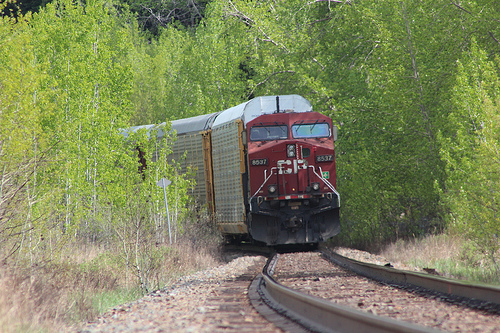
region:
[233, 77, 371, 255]
front of the train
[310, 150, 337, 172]
number on the front of the train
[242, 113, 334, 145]
windows on front of train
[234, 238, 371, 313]
track under the train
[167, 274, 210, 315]
rocks next to the track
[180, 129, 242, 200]
side of the train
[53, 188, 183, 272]
branches next to track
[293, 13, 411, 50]
leaves on the tree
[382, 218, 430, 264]
shadow on the ground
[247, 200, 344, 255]
bottom of the train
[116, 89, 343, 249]
A train with red paint on the front.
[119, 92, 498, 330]
A train traveling down train tracks.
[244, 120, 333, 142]
Two windows on the front of a train.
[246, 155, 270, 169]
A number in white letters.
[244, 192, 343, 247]
A black metal plate on the bottom of a train.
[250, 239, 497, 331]
Curvy train tracks.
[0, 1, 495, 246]
A large amount of trees that are mostly green.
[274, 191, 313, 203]
Red and white paint.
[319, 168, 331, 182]
A small green and white symbol.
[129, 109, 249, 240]
Cars of a train.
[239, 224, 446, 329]
These are train tracks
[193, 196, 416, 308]
The tracks are rusty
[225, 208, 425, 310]
The tracks are made of metal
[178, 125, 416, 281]
This is a large train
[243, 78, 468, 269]
The train is red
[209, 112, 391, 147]
These are two windows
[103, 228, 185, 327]
These are tiny stones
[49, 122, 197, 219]
These are old bushes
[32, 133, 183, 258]
The trees are very light green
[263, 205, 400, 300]
This part of the train is black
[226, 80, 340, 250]
train's front is red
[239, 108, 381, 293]
train's front is red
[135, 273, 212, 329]
pebbles on the ground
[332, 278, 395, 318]
pebbles on the ground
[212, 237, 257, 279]
pebbles on the ground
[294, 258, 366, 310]
pebbles on the ground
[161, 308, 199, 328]
pebbles on the ground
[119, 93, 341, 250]
the train on the track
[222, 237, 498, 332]
the train track on the ground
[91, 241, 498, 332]
the rocks near the train tracks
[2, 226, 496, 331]
the brown grass near the train tracks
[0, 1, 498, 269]
the green trees around the train track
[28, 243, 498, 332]
the patches of green grass near the track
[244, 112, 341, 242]
the front of the train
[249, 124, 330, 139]
the windows on the front of the train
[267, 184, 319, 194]
the lights on the front of the train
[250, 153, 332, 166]
the numbers on the front of the train